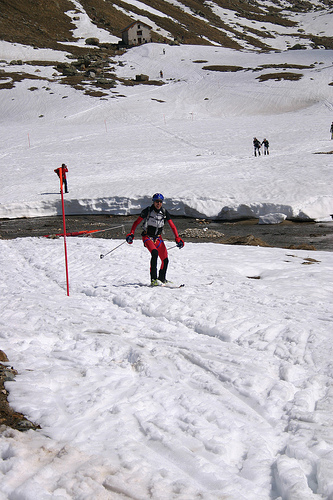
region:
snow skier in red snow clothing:
[96, 192, 213, 290]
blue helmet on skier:
[150, 190, 165, 201]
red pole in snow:
[56, 166, 75, 298]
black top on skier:
[138, 202, 175, 240]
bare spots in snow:
[241, 252, 321, 281]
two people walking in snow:
[250, 134, 270, 156]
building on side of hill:
[120, 18, 154, 46]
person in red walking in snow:
[54, 162, 70, 191]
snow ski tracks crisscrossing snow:
[26, 304, 329, 499]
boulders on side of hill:
[57, 35, 150, 91]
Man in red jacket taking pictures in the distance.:
[54, 163, 69, 191]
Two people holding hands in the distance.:
[252, 137, 269, 155]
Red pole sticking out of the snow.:
[59, 167, 69, 294]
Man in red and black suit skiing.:
[126, 193, 184, 286]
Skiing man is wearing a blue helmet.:
[153, 192, 163, 199]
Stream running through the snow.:
[1, 216, 332, 250]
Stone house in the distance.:
[122, 19, 152, 44]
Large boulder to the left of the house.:
[86, 37, 97, 45]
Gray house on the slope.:
[121, 20, 151, 48]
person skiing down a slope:
[101, 193, 187, 290]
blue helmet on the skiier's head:
[151, 192, 163, 200]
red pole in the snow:
[56, 162, 71, 296]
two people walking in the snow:
[250, 136, 275, 157]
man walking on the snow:
[53, 160, 69, 192]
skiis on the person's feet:
[131, 278, 212, 294]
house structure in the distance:
[120, 22, 157, 44]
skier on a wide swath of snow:
[29, 187, 322, 412]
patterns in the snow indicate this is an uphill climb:
[39, 238, 313, 356]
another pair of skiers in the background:
[249, 133, 274, 160]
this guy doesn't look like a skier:
[51, 158, 73, 195]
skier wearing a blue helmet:
[148, 190, 169, 211]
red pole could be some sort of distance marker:
[53, 164, 82, 302]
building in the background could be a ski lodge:
[116, 14, 159, 51]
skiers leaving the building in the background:
[155, 45, 168, 82]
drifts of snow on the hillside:
[14, 0, 314, 47]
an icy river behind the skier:
[2, 204, 330, 262]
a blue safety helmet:
[151, 193, 162, 200]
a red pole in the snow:
[58, 167, 68, 295]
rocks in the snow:
[0, 352, 34, 430]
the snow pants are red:
[143, 236, 168, 281]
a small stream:
[4, 214, 329, 250]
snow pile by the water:
[219, 203, 302, 221]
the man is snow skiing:
[99, 191, 186, 290]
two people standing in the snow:
[250, 136, 269, 155]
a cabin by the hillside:
[119, 19, 150, 44]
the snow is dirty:
[20, 434, 156, 496]